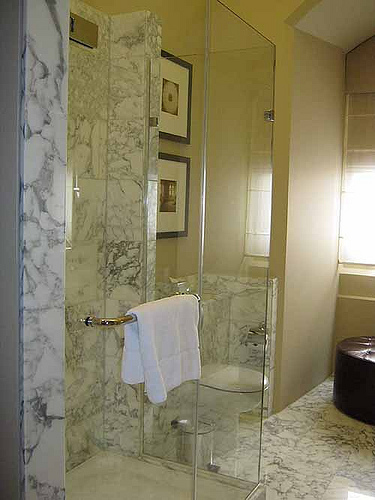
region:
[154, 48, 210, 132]
framed painting on wall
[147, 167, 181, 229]
framed painting on wall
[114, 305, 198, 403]
white towel on bar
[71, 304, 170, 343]
metal bar on wall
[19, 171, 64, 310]
granite walls in bathroom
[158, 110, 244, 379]
sliding glass shower door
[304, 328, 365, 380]
red seat on right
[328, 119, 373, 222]
window in bath room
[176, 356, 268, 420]
white toilet behind glass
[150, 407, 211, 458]
metal trash can near toilet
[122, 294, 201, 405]
Bath towel hanging on a rack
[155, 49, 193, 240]
Two pictures on the wall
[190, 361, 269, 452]
White porcelain toilet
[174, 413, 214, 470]
Trash bin beside toilet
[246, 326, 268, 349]
Metal toilet paper dispenser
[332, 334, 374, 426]
Dark brown cushioned stool in front of window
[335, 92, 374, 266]
Brightly lit window with curtains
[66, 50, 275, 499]
Glass shower enclosure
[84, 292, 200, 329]
Metal bathroom towel rack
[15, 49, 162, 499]
Stone tiled shower wall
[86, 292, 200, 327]
a metal bar on the shower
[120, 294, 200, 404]
a towel hanging on the bar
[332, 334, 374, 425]
a leather ottoman seat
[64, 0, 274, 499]
a glass shower enclosure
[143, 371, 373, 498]
a marble tiled floor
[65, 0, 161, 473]
a marble tiled shower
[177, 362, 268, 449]
a white toilet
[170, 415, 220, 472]
a small metal wastebasket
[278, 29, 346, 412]
a beige bathroom wall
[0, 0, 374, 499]
the interior of a bathroom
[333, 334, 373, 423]
a brown leather seat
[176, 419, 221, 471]
a metal trash can by the toilet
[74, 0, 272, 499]
a glass enclosed shower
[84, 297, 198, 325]
a metal rod on the shower door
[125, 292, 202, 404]
a white towel hanging on metal rod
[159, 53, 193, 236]
two pieces of art above the toilet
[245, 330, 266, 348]
toilet paper roll holder with no toilet paper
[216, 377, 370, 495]
a white marble floor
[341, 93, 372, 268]
a window in the bathroom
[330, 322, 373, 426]
the ottoman is round & brown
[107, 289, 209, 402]
the towel is white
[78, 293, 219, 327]
the towel bar is gold tone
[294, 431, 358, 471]
the floor is marble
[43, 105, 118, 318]
the wall is marble as well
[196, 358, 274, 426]
the toilet is white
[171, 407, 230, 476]
the trash can is a step to open type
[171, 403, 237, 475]
the trash can is chrome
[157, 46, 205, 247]
pictures hang on the wall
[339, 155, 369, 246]
the window is frosted